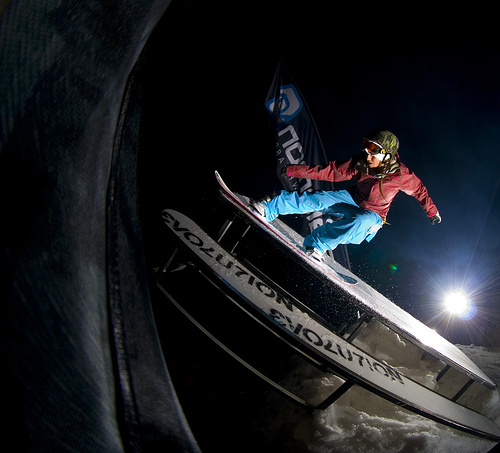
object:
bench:
[208, 170, 496, 402]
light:
[405, 235, 500, 351]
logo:
[266, 83, 303, 125]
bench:
[150, 203, 500, 445]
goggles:
[363, 139, 391, 161]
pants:
[264, 189, 384, 253]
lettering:
[160, 209, 405, 387]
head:
[362, 130, 400, 169]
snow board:
[212, 170, 360, 287]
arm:
[399, 164, 435, 211]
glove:
[429, 211, 442, 226]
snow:
[315, 314, 499, 453]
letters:
[274, 123, 334, 234]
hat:
[364, 131, 400, 160]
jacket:
[286, 151, 438, 223]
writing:
[159, 207, 406, 386]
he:
[247, 130, 442, 262]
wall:
[138, 168, 500, 453]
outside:
[0, 0, 500, 453]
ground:
[309, 322, 500, 453]